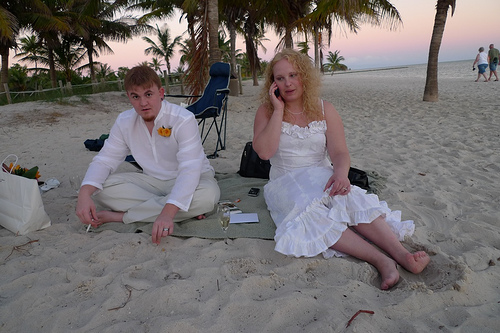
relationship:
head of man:
[122, 66, 167, 124] [73, 64, 225, 243]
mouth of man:
[140, 106, 153, 114] [73, 64, 225, 243]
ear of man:
[159, 85, 167, 99] [73, 64, 225, 243]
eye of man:
[145, 91, 153, 98] [73, 64, 225, 243]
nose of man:
[139, 98, 149, 109] [73, 64, 225, 243]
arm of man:
[162, 136, 207, 213] [73, 64, 225, 243]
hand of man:
[148, 214, 175, 243] [73, 64, 225, 243]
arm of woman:
[323, 101, 353, 197] [249, 48, 432, 291]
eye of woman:
[289, 71, 297, 79] [249, 48, 432, 291]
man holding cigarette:
[73, 64, 225, 243] [85, 216, 94, 232]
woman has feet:
[249, 48, 432, 291] [374, 246, 431, 291]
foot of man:
[92, 207, 126, 224] [73, 64, 225, 243]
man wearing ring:
[73, 64, 225, 243] [162, 226, 169, 233]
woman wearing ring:
[249, 48, 432, 291] [340, 184, 350, 192]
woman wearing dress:
[249, 48, 432, 291] [258, 92, 425, 259]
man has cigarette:
[73, 64, 225, 243] [85, 216, 94, 232]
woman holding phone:
[249, 48, 432, 291] [270, 82, 281, 100]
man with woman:
[73, 64, 225, 243] [249, 48, 432, 291]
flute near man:
[214, 204, 231, 246] [73, 64, 225, 243]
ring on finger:
[162, 226, 169, 233] [152, 228, 165, 246]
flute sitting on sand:
[207, 201, 241, 248] [44, 234, 286, 320]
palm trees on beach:
[1, 0, 459, 106] [11, 65, 481, 323]